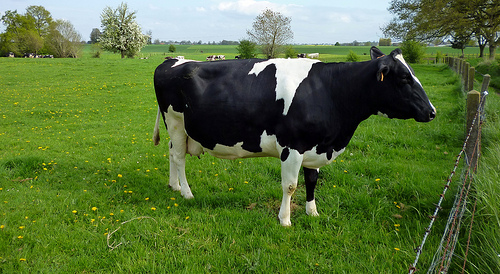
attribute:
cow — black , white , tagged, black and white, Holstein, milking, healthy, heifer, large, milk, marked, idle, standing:
[148, 41, 437, 228]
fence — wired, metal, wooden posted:
[403, 47, 497, 271]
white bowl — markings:
[149, 37, 448, 230]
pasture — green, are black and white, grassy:
[5, 230, 498, 270]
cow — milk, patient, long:
[180, 57, 417, 209]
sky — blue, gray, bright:
[0, 0, 393, 44]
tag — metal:
[376, 72, 384, 80]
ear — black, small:
[377, 56, 389, 78]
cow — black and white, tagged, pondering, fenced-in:
[128, 31, 447, 242]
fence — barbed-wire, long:
[406, 52, 491, 267]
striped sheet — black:
[148, 36, 440, 230]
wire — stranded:
[399, 43, 489, 270]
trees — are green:
[2, 5, 82, 57]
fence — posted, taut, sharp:
[399, 49, 486, 273]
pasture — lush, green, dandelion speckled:
[2, 42, 497, 272]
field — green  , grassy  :
[9, 71, 496, 266]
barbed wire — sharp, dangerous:
[409, 102, 481, 272]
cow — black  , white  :
[142, 53, 451, 247]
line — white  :
[397, 50, 441, 113]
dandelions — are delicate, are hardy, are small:
[70, 205, 125, 223]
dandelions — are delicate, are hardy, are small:
[40, 158, 60, 169]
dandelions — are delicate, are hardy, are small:
[162, 195, 180, 211]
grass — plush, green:
[0, 57, 200, 272]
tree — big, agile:
[97, 6, 146, 61]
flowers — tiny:
[121, 20, 135, 33]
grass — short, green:
[207, 153, 325, 272]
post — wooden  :
[466, 90, 480, 172]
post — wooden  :
[480, 73, 490, 117]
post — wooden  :
[467, 64, 474, 90]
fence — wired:
[405, 100, 490, 270]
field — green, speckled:
[14, 54, 275, 230]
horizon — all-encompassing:
[1, 31, 483, 59]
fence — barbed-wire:
[427, 27, 484, 245]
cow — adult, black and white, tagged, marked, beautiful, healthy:
[140, 24, 437, 246]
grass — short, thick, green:
[17, 157, 337, 256]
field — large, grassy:
[15, 38, 419, 258]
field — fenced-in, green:
[0, 33, 429, 251]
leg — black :
[301, 165, 324, 216]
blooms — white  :
[132, 20, 136, 26]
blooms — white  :
[135, 34, 142, 41]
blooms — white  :
[104, 38, 113, 47]